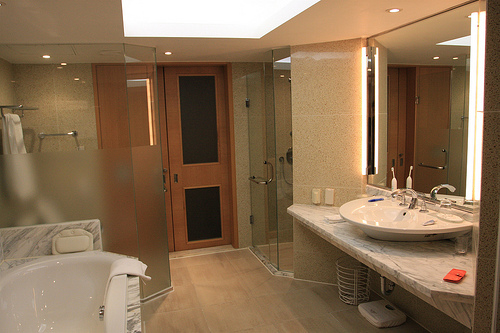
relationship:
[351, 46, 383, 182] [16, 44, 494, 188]
lighting in bathroom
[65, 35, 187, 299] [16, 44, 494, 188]
double sliding door in bathroom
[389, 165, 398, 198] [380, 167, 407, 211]
electric toothbrush in holder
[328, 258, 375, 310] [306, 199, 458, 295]
waste basket under counter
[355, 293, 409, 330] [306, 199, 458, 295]
white scale under counter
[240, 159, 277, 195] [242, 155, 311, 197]
silver towel bar on wall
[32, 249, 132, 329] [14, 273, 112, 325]
jacuzzi that white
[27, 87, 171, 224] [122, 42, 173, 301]
walk in shower with double sliding door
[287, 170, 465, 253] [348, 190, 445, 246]
modern style white bathroom sink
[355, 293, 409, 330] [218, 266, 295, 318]
white scale on floor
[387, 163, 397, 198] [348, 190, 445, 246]
electric toothbrush on sink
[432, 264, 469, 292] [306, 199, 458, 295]
orange purse on counter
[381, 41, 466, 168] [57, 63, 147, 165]
reflection of shower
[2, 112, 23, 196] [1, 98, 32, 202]
white towels hanging down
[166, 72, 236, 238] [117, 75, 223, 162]
wooden door with 2 windows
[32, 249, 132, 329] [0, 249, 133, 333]
empty white jacuzzi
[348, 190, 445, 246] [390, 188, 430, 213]
white sink with silver faucet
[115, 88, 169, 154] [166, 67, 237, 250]
window inside of a wooden door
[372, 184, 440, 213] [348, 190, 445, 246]
silver faucet above a sink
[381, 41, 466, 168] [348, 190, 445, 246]
mirror above a sink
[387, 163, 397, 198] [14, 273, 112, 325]
electric toothbrush that white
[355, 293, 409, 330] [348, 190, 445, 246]
bathroom scale under sink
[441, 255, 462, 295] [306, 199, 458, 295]
red wallet on counter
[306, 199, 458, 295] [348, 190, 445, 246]
counter above sink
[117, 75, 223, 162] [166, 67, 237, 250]
two tone wooden wooden door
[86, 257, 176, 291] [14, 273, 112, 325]
white towel over edge of tub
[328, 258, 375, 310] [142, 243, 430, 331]
wire basket in floor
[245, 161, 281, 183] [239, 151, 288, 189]
silver metal handle to shower door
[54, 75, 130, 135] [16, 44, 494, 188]
glass wall in bathroom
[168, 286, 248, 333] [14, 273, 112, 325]
marbled tile around edge of tub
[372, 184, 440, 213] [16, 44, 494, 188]
silver faucet in bathroom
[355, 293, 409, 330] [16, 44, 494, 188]
white scale in bathroom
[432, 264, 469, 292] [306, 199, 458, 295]
orange case on counter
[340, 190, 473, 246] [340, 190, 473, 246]
bathroom sink of bathroom sink